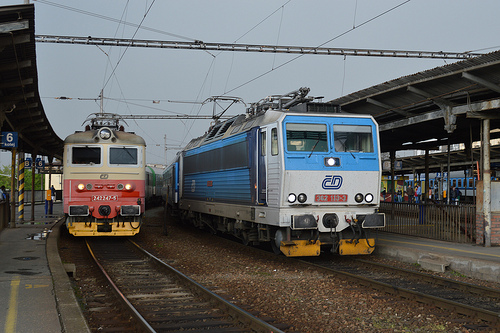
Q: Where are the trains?
A: Side by Side.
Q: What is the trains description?
A: Blue and Silver.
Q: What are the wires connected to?
A: The train.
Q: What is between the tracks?
A: Gravel on the ground.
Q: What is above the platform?
A: A roof.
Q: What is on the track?
A: Blue Train.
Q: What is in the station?
A: Two trains.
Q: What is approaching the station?
A: A train.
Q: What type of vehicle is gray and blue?
A: Train.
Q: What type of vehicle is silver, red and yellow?
A: Train.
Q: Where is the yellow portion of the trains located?
A: At the bottom.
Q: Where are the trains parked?
A: Train station.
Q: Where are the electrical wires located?
A: Above trains.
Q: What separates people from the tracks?
A: Fence.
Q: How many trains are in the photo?
A: Two.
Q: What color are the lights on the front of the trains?
A: Orange.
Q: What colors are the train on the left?
A: Red, White, Yellow.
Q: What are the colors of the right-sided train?
A: Blue, Grey.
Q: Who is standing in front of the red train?
A: No one.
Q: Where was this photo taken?
A: At a train station.